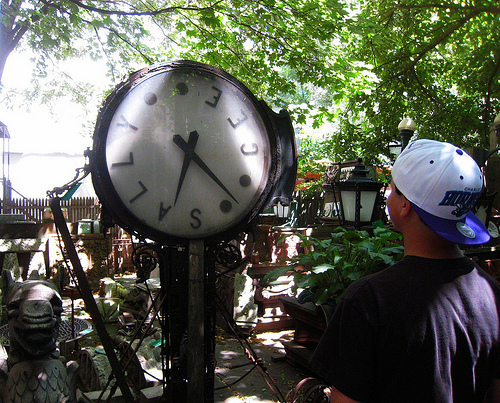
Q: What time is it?
A: 6:24.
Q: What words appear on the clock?
A: Sally Cee.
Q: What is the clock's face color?
A: White.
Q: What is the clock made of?
A: Metal.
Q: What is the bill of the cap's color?
A: Blue.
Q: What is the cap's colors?
A: White and Blue.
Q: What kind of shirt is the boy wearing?
A: T-Shirt.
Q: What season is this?
A: Summer.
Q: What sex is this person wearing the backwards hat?
A: Male.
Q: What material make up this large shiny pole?
A: Metal.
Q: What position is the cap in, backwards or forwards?
A: Backwards.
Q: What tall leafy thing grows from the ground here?
A: Tree.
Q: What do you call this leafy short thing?
A: Plant.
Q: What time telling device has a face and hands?
A: Clock.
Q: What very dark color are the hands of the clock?
A: Black.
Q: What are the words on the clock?
A: Sally Cee.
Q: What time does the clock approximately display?
A: 7:25.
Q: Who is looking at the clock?
A: The man with the white and blue cap.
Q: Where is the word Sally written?
A: On the left side of the clock face.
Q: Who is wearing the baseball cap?
A: The man on the right side of the clock.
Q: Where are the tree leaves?
A: Above the clock and the man.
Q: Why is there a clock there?
A: To let the time be known.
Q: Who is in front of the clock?
A: A man.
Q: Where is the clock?
A: Outside on the street.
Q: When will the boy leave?
A: After he has read the time.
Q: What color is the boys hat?
A: White.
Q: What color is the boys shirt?
A: Blue.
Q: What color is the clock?
A: Black.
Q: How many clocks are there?
A: One.